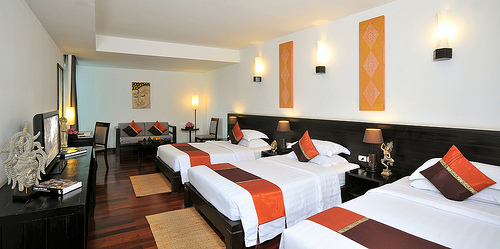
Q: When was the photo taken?
A: Day time.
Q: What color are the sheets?
A: White.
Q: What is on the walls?
A: Lights.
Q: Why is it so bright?
A: Lights are on.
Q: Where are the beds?
A: Right wall.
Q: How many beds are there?
A: Three.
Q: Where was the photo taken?
A: In a hotel.